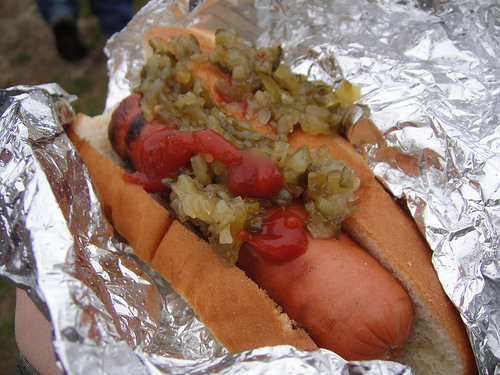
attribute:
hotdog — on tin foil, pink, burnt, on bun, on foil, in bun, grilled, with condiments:
[110, 91, 414, 359]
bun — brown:
[68, 26, 482, 370]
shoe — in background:
[53, 17, 83, 60]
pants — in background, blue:
[38, 2, 131, 23]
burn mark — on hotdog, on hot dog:
[123, 114, 144, 146]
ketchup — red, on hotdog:
[140, 132, 308, 259]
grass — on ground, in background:
[73, 79, 91, 94]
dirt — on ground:
[31, 59, 53, 79]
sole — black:
[59, 26, 80, 60]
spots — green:
[9, 52, 90, 88]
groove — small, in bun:
[147, 211, 173, 271]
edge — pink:
[322, 272, 410, 358]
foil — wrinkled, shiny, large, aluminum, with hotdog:
[3, 1, 498, 374]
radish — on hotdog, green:
[137, 37, 358, 238]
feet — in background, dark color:
[55, 15, 121, 60]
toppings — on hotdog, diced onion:
[138, 30, 360, 254]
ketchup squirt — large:
[134, 128, 282, 197]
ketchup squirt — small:
[238, 212, 308, 260]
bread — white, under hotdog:
[407, 324, 458, 374]